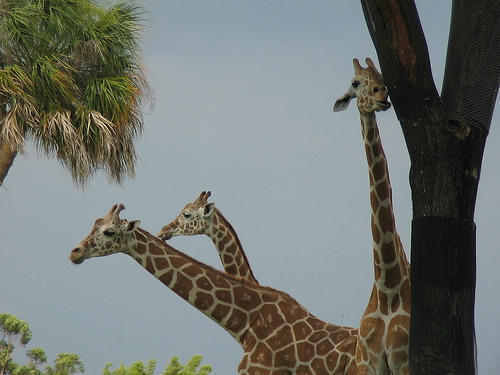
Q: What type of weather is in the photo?
A: It is overcast.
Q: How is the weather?
A: It is overcast.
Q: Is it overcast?
A: Yes, it is overcast.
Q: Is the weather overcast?
A: Yes, it is overcast.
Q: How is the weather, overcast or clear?
A: It is overcast.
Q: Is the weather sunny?
A: No, it is overcast.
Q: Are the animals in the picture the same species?
A: Yes, all the animals are giraffes.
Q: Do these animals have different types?
A: No, all the animals are giraffes.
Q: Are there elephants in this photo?
A: No, there are no elephants.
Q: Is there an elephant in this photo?
A: No, there are no elephants.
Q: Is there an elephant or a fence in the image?
A: No, there are no elephants or fences.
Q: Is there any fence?
A: No, there are no fences.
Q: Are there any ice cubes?
A: No, there are no ice cubes.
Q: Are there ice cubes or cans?
A: No, there are no ice cubes or cans.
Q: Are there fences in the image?
A: No, there are no fences.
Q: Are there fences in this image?
A: No, there are no fences.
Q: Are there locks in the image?
A: No, there are no locks.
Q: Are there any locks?
A: No, there are no locks.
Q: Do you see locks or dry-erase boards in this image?
A: No, there are no locks or dry-erase boards.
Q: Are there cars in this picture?
A: No, there are no cars.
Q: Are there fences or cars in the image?
A: No, there are no cars or fences.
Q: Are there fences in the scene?
A: No, there are no fences.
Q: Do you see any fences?
A: No, there are no fences.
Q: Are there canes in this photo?
A: No, there are no canes.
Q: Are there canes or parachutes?
A: No, there are no canes or parachutes.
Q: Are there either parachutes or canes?
A: No, there are no canes or parachutes.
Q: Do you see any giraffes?
A: Yes, there is a giraffe.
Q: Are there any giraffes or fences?
A: Yes, there is a giraffe.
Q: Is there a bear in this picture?
A: No, there are no bears.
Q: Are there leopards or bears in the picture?
A: No, there are no bears or leopards.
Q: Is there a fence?
A: No, there are no fences.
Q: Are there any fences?
A: No, there are no fences.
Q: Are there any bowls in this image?
A: No, there are no bowls.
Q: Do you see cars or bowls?
A: No, there are no bowls or cars.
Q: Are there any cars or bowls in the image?
A: No, there are no bowls or cars.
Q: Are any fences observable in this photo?
A: No, there are no fences.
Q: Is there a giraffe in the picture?
A: Yes, there is a giraffe.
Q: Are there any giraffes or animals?
A: Yes, there is a giraffe.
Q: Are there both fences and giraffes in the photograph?
A: No, there is a giraffe but no fences.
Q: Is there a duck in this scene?
A: No, there are no ducks.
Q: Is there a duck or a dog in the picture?
A: No, there are no ducks or dogs.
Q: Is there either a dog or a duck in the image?
A: No, there are no ducks or dogs.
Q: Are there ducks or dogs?
A: No, there are no ducks or dogs.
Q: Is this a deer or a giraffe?
A: This is a giraffe.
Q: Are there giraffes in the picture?
A: Yes, there is a giraffe.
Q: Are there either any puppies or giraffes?
A: Yes, there is a giraffe.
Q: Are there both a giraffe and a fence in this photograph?
A: No, there is a giraffe but no fences.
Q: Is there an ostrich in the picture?
A: No, there are no ostriches.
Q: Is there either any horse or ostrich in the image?
A: No, there are no ostriches or horses.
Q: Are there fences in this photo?
A: No, there are no fences.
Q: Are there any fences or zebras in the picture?
A: No, there are no fences or zebras.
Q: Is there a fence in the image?
A: No, there are no fences.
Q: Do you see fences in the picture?
A: No, there are no fences.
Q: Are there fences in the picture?
A: No, there are no fences.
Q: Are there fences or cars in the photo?
A: No, there are no fences or cars.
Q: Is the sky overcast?
A: Yes, the sky is overcast.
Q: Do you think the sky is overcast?
A: Yes, the sky is overcast.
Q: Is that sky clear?
A: No, the sky is overcast.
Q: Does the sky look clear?
A: No, the sky is overcast.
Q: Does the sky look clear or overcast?
A: The sky is overcast.